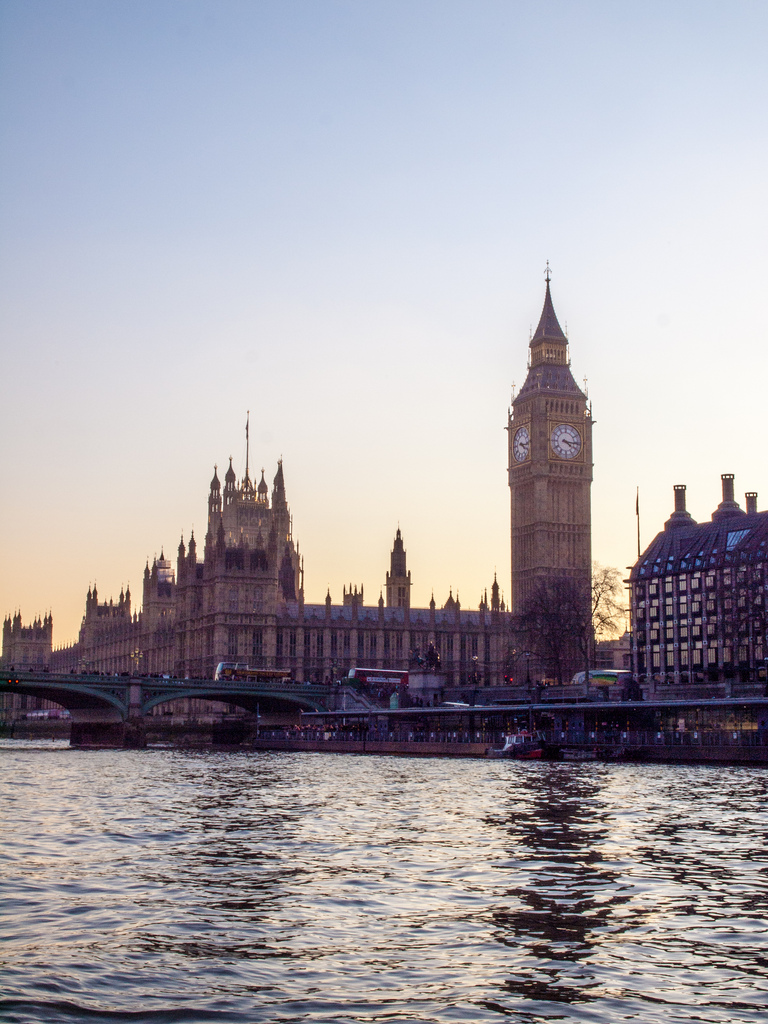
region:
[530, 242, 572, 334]
Sharp pointed building tower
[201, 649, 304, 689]
Vehicle passing on top of bridge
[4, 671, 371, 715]
Bridge running across a water body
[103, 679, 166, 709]
Green colored strong metal bridge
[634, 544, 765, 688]
Storied building beside a water body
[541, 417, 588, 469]
Watch showing in Roman numerals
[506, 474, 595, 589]
Brown colored brick tower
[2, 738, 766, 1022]
A dark reflecting rippled body of water.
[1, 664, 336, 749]
A green two arched bridge.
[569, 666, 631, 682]
The top of a white and green bus.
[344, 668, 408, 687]
A red and white bus.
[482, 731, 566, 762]
A small white and red boat against the concrete.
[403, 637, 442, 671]
Statue with horses on top.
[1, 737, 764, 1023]
A rippled dark body of water.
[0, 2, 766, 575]
A long blue sky that fades into grey.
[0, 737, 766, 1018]
a large body of water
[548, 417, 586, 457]
a black and white building clock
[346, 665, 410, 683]
a long red and white bus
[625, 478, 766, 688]
a large building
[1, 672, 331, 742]
a long green bridge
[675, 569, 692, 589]
a window of a building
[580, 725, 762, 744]
a long fence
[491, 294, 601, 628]
tall brown clock tower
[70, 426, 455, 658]
large brown building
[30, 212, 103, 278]
white clouds in blue sky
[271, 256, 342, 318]
white clouds in blue sky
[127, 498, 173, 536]
white clouds in blue sky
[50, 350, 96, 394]
white clouds in blue sky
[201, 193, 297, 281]
white clouds in blue sky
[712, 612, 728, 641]
a window on the building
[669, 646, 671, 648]
a window on the building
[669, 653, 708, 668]
a window on the building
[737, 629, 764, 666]
a window on the building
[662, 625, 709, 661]
a window on the building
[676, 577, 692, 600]
a window on the building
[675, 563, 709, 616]
a window on the building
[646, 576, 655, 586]
glass window on the building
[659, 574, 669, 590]
glass window on the building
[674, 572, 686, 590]
glass window on the building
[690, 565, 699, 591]
glass window on the building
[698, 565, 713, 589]
glass window on the building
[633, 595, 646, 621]
glass window on the building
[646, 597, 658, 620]
glass window on the building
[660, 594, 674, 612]
glass window on the building